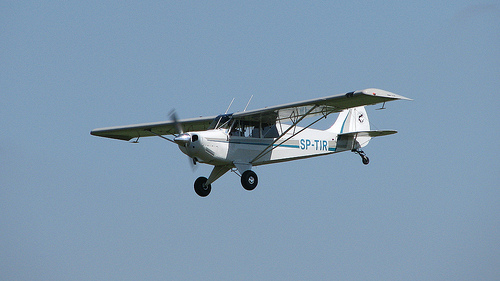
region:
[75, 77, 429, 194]
Airplane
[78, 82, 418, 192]
This is a biplane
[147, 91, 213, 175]
The front propeller is spinning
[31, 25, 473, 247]
There are no clouds in the sky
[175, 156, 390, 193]
The plane has just three wheels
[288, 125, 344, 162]
SP-TIR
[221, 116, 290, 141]
The plane has one large window on the side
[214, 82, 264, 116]
Two antennae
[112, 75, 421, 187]
This is not a corporate plane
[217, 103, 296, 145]
No passengers are visible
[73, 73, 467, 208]
an aeroplane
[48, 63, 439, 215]
an airplane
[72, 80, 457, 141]
the wing on an airplane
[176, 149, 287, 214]
the landing gear on an airplane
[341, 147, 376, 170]
the tail wheel of an airplane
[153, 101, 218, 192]
the propeller on an airplane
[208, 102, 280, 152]
the cockpit of an airplane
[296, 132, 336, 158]
the tail numbers on an airplane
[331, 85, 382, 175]
the tail rudder of an airplane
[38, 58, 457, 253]
an airplane flying in the sky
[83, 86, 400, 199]
a little plane flying in the air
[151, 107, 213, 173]
the propellor of the plane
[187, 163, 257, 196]
the wheels of the plane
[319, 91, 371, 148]
the tail of the plane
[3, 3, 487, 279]
the blue sky in the cloudless sky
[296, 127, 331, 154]
the writing on the side of the plane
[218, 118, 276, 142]
the windows on the plane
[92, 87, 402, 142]
the wings of the plane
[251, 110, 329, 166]
the poles holding up the wing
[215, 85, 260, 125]
the top of the plane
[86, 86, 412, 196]
a white airplane with blue and gray stripes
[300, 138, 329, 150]
SP-TIR on the side of the airplane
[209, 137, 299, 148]
gray and blue stripes on the white airplane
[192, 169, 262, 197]
two front wheels on the airplane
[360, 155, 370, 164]
one small black tire on the back of the white airplane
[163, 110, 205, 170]
the propeller in motion on the airplane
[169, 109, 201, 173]
a turning propeller on the front of the white airplane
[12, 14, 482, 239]
an airplane flying below the blue sky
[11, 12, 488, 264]
a white airplane flying in the air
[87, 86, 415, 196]
a white airplane preparing for landing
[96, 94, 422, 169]
Airplane in the sky.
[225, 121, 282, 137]
Windows on airplane.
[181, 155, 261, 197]
Two front wheels on plane.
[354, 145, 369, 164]
Small wheel on tail.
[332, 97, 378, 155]
Tail on airplane.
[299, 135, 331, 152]
Blue writing on side of plane.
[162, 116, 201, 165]
A spinning airplane propeller.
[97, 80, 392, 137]
Wings across top of plane.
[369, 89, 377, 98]
Red light on wing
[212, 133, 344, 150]
Stripe down side of plane.